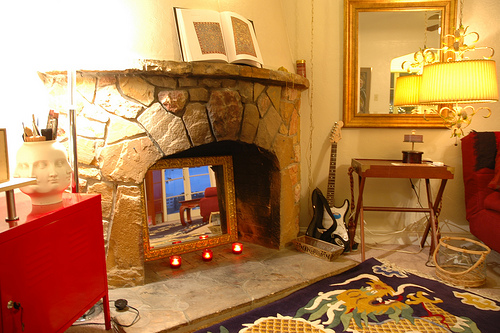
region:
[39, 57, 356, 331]
stone fireplace in living room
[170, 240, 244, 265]
three red candles lit in fireplace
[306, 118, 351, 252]
black guitar behind stone fireplace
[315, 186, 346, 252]
guitar covered by black guitar strap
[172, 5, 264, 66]
large book on top of fireplace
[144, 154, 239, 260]
mirror inside of fireplace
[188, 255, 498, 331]
carpet on floor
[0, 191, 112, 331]
red side table next to fireplace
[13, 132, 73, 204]
white vase on side table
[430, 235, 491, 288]
wooden basket next to carpet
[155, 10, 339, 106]
book on the mantle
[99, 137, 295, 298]
the candle holders are red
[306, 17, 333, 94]
the wall is yellow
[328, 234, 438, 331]
the rug is on the floor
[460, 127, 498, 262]
the couch is red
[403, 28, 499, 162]
the lamp is yellow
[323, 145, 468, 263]
the table is brown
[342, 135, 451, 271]
the table is made of wood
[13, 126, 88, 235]
the brush holder has face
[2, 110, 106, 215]
the brush holder is white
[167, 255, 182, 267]
Red candle light in front of mirror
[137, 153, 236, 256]
Mirror inside of chimney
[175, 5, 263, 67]
Book on top of chimney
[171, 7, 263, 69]
Book is open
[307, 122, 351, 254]
Black and white guitar next to chimney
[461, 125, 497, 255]
Red sofa next to lit light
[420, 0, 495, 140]
Light next to mirror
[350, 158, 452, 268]
Small desk next to guitar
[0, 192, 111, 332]
Red desk next to chimney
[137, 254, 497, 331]
Rug in front of chimney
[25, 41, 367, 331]
fireplace in a room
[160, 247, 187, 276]
candle in a fireplace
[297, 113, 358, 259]
guitar leaning against a wall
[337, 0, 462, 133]
mirror on a wall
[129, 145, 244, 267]
mirror in a fireplace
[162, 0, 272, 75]
book on a fireplace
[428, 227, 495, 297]
basket on a floor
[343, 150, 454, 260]
brown table on a floor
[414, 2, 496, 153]
light hanging from a ceiling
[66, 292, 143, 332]
electrical wire on a floor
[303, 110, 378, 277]
a black and white guitar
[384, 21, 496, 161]
the lamp is on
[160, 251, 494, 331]
the carpet has a dragon on it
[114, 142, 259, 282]
a mirror in the fireplace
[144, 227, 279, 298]
three red candles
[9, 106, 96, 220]
pencils in a container shaped like a face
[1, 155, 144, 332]
the stand is red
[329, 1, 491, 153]
the frame on the mirror is gold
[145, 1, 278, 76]
an open book on the fireplace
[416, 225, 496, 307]
a small basket